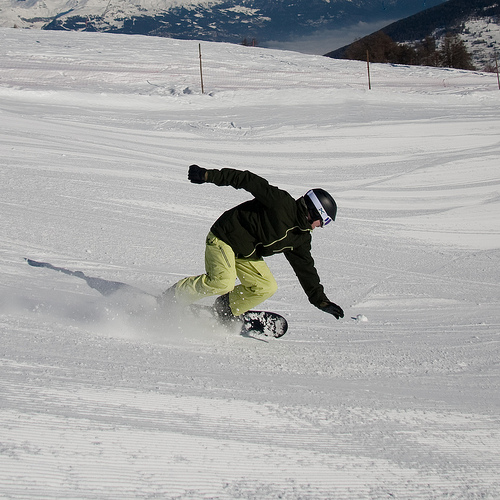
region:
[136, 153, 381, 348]
a man riding down a snow covered slope.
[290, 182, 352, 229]
a man wearing a helmet.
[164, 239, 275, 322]
a pair of yellow pants.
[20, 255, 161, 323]
a shadow cast on snow.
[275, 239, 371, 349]
a left human arm.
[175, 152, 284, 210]
a right human arm.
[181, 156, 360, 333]
a black jacket on a man.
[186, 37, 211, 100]
a pole sticking in the snow.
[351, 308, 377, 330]
a small pile of snow.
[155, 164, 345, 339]
Man snowboarding on black snowboard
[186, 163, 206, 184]
Black glove on man's hand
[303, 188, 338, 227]
Black helmet on man's head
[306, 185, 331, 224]
Gray stripe on man's helmet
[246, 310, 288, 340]
Snow stuck on bottom of black snowboard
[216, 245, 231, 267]
Zipper on front of yellow pants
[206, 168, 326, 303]
Black snow coat with white stripe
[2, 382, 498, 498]
Grooved and packed down snow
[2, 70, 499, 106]
Ridge on top of snowy mountain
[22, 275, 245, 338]
Snow flying up into air from snowboard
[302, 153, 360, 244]
the head of a man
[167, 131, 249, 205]
the hand of a man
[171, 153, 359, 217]
the arm of a man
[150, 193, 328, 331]
the legs of a man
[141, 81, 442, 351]
a man in the snow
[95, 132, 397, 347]
a man on a snowboard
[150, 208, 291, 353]
a man wearing pants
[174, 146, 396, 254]
a man wearing a shirt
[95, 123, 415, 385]
a man sliding on snow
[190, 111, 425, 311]
the body of a man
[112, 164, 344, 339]
a person snowboarding down the mountain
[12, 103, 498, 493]
snow-covered ski slope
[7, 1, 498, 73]
more mountains on the horizon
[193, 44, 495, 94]
wooden poles in the snow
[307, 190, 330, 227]
white snow goggles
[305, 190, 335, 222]
black ski helmet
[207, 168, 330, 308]
black ski jacket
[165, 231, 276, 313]
snowboarder wearing yellow ski pants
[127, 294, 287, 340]
a black snowboard covered in snow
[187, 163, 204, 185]
the snowboarder's right hand in a fist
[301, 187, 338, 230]
Black helmet with white band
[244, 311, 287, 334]
Snowboard with snow flying around it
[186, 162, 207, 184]
Solid black winter glove on hand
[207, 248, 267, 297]
Tan snowboard pants with zippers on legs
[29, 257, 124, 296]
Grey shadow in the snow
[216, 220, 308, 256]
Black snowboard jacket with grey zipper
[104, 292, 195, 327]
Powdered snow flying up under snowboard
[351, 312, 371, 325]
Small ball of white snow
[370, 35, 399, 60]
Bare brown trees in skyline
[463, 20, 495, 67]
Snow covered mountain in skyline